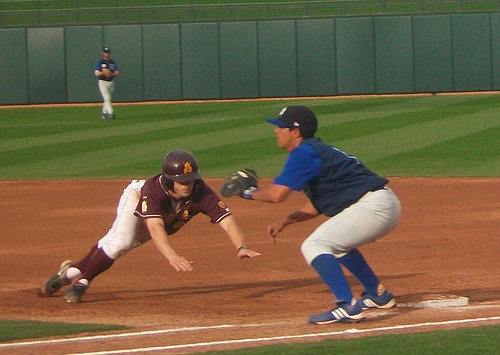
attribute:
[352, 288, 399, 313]
cleat — blue, white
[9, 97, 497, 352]
field — green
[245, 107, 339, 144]
hat — blue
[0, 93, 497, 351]
baseball field — dirt covered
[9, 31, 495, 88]
wall — green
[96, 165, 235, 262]
uniform — white, burgundy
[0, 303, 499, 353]
lines — white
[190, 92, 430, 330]
uniform — white, blue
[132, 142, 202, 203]
helmet — burgundy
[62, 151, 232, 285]
uniform — maroon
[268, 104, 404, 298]
uniform — blue